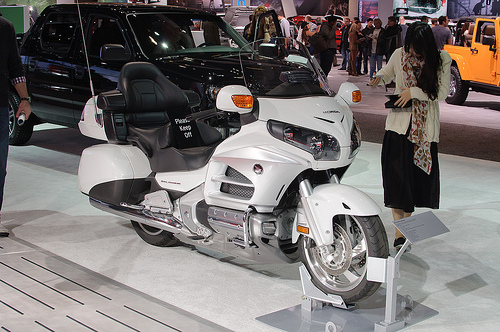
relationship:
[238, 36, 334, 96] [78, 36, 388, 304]
windshield of motorcycle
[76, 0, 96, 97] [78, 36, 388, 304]
antenna of motorcycle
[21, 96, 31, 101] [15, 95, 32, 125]
watch on wrist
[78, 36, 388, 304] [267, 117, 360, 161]
motorcycle has headlight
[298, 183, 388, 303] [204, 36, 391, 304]
wheel on front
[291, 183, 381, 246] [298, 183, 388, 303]
fender on wheel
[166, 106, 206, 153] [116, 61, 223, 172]
sign on seat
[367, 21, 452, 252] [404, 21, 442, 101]
woman with hair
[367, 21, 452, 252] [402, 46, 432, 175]
woman wearing scarf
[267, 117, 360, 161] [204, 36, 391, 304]
headlight on front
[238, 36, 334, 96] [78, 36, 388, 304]
windshield on vehicle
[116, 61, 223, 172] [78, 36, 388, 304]
seat of motorcycle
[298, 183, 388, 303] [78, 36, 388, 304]
wheel of motorcycle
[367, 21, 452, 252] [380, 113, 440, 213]
woman wearing skirt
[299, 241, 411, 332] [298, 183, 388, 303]
support of wheel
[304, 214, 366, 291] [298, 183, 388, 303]
spokes of wheel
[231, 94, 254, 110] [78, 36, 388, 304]
light on motorcycle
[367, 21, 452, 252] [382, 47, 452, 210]
woman in dress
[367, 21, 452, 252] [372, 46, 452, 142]
woman wearing shirt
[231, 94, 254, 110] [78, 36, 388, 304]
light of motorcycle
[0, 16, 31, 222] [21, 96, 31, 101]
man wearing watch